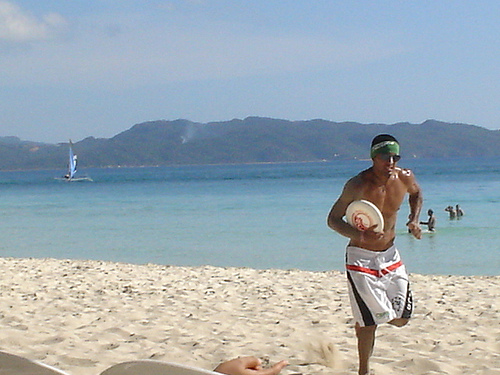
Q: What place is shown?
A: It is a beach.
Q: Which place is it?
A: It is a beach.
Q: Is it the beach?
A: Yes, it is the beach.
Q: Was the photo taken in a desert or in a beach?
A: It was taken at a beach.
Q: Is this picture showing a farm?
A: No, the picture is showing a beach.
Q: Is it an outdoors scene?
A: Yes, it is outdoors.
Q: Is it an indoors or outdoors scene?
A: It is outdoors.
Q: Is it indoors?
A: No, it is outdoors.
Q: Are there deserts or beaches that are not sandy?
A: No, there is a beach but it is sandy.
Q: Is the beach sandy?
A: Yes, the beach is sandy.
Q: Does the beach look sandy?
A: Yes, the beach is sandy.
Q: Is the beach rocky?
A: No, the beach is sandy.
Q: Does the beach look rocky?
A: No, the beach is sandy.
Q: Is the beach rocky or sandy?
A: The beach is sandy.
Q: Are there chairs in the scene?
A: Yes, there is a chair.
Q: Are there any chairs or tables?
A: Yes, there is a chair.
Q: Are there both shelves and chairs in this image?
A: No, there is a chair but no shelves.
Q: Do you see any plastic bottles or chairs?
A: Yes, there is a plastic chair.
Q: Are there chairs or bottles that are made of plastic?
A: Yes, the chair is made of plastic.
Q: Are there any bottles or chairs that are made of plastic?
A: Yes, the chair is made of plastic.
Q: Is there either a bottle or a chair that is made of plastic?
A: Yes, the chair is made of plastic.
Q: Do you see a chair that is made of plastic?
A: Yes, there is a chair that is made of plastic.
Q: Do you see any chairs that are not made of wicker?
A: Yes, there is a chair that is made of plastic.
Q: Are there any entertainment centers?
A: No, there are no entertainment centers.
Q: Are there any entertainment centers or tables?
A: No, there are no entertainment centers or tables.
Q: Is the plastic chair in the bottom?
A: Yes, the chair is in the bottom of the image.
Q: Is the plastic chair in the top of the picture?
A: No, the chair is in the bottom of the image.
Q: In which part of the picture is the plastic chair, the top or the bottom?
A: The chair is in the bottom of the image.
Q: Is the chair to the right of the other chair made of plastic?
A: Yes, the chair is made of plastic.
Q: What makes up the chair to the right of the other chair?
A: The chair is made of plastic.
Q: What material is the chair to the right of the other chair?
A: The chair is made of plastic.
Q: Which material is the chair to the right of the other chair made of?
A: The chair is made of plastic.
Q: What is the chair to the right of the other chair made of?
A: The chair is made of plastic.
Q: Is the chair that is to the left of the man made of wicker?
A: No, the chair is made of plastic.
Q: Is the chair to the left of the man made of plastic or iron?
A: The chair is made of plastic.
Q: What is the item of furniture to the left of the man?
A: The piece of furniture is a chair.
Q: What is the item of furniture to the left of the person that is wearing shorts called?
A: The piece of furniture is a chair.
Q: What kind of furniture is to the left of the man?
A: The piece of furniture is a chair.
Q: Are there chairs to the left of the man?
A: Yes, there is a chair to the left of the man.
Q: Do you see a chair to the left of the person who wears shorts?
A: Yes, there is a chair to the left of the man.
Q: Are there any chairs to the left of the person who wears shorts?
A: Yes, there is a chair to the left of the man.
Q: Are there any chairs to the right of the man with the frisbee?
A: No, the chair is to the left of the man.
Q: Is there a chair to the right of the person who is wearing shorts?
A: No, the chair is to the left of the man.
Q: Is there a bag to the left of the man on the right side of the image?
A: No, there is a chair to the left of the man.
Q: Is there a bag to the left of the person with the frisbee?
A: No, there is a chair to the left of the man.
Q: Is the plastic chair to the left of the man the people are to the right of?
A: Yes, the chair is to the left of the man.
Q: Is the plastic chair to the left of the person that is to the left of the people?
A: Yes, the chair is to the left of the man.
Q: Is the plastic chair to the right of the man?
A: No, the chair is to the left of the man.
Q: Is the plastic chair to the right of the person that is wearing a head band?
A: No, the chair is to the left of the man.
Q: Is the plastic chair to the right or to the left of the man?
A: The chair is to the left of the man.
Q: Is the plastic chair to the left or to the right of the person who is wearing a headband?
A: The chair is to the left of the man.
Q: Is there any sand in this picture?
A: Yes, there is sand.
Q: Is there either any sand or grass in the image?
A: Yes, there is sand.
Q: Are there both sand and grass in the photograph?
A: No, there is sand but no grass.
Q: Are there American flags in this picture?
A: No, there are no American flags.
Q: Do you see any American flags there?
A: No, there are no American flags.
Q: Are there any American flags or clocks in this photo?
A: No, there are no American flags or clocks.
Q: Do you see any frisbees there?
A: Yes, there is a frisbee.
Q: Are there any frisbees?
A: Yes, there is a frisbee.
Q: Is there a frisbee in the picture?
A: Yes, there is a frisbee.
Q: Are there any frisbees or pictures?
A: Yes, there is a frisbee.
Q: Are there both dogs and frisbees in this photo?
A: No, there is a frisbee but no dogs.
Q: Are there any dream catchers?
A: No, there are no dream catchers.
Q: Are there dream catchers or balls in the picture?
A: No, there are no dream catchers or balls.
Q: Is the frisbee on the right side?
A: Yes, the frisbee is on the right of the image.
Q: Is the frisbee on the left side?
A: No, the frisbee is on the right of the image.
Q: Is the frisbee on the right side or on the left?
A: The frisbee is on the right of the image.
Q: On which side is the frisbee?
A: The frisbee is on the right of the image.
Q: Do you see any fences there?
A: No, there are no fences.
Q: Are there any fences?
A: No, there are no fences.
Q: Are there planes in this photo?
A: No, there are no planes.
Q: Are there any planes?
A: No, there are no planes.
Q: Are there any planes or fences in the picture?
A: No, there are no planes or fences.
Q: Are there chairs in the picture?
A: Yes, there is a chair.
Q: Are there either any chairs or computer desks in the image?
A: Yes, there is a chair.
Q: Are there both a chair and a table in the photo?
A: No, there is a chair but no tables.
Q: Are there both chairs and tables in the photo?
A: No, there is a chair but no tables.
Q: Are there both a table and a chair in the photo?
A: No, there is a chair but no tables.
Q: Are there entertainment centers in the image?
A: No, there are no entertainment centers.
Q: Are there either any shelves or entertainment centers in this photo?
A: No, there are no entertainment centers or shelves.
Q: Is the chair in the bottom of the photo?
A: Yes, the chair is in the bottom of the image.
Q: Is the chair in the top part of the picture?
A: No, the chair is in the bottom of the image.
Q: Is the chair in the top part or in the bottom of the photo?
A: The chair is in the bottom of the image.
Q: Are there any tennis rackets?
A: No, there are no tennis rackets.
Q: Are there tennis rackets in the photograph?
A: No, there are no tennis rackets.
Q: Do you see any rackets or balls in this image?
A: No, there are no rackets or balls.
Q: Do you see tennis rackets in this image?
A: No, there are no tennis rackets.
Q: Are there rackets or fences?
A: No, there are no rackets or fences.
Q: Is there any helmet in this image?
A: No, there are no helmets.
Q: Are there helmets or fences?
A: No, there are no helmets or fences.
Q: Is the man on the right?
A: Yes, the man is on the right of the image.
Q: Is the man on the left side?
A: No, the man is on the right of the image.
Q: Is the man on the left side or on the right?
A: The man is on the right of the image.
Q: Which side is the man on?
A: The man is on the right of the image.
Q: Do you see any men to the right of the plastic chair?
A: Yes, there is a man to the right of the chair.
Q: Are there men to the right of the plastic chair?
A: Yes, there is a man to the right of the chair.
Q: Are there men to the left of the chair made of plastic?
A: No, the man is to the right of the chair.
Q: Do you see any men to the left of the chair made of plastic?
A: No, the man is to the right of the chair.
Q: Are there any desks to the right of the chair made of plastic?
A: No, there is a man to the right of the chair.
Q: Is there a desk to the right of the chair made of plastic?
A: No, there is a man to the right of the chair.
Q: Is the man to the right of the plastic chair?
A: Yes, the man is to the right of the chair.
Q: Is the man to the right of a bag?
A: No, the man is to the right of the chair.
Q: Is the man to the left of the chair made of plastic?
A: No, the man is to the right of the chair.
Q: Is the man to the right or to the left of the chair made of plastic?
A: The man is to the right of the chair.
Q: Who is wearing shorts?
A: The man is wearing shorts.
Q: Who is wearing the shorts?
A: The man is wearing shorts.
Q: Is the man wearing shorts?
A: Yes, the man is wearing shorts.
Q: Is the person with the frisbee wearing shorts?
A: Yes, the man is wearing shorts.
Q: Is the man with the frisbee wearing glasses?
A: No, the man is wearing shorts.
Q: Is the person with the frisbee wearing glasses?
A: No, the man is wearing shorts.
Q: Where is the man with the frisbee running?
A: The man is running on the beach.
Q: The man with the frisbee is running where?
A: The man is running on the beach.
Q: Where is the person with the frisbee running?
A: The man is running on the beach.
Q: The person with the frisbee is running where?
A: The man is running on the beach.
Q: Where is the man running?
A: The man is running on the beach.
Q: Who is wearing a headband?
A: The man is wearing a headband.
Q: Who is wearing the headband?
A: The man is wearing a headband.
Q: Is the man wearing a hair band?
A: Yes, the man is wearing a hair band.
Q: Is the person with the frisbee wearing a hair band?
A: Yes, the man is wearing a hair band.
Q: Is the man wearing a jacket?
A: No, the man is wearing a hair band.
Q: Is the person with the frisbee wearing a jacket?
A: No, the man is wearing a hair band.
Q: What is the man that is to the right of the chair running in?
A: The man is running in the sand.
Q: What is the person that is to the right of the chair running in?
A: The man is running in the sand.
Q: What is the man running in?
A: The man is running in the sand.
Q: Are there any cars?
A: No, there are no cars.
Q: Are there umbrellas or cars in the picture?
A: No, there are no cars or umbrellas.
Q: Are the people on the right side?
A: Yes, the people are on the right of the image.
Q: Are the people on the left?
A: No, the people are on the right of the image.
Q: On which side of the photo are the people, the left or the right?
A: The people are on the right of the image.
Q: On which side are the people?
A: The people are on the right of the image.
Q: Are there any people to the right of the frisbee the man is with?
A: Yes, there are people to the right of the frisbee.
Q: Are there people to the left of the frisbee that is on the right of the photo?
A: No, the people are to the right of the frisbee.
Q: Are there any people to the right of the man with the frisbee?
A: Yes, there are people to the right of the man.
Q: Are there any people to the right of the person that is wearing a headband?
A: Yes, there are people to the right of the man.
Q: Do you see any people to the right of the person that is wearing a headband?
A: Yes, there are people to the right of the man.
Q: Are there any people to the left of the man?
A: No, the people are to the right of the man.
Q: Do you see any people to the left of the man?
A: No, the people are to the right of the man.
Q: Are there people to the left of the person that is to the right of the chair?
A: No, the people are to the right of the man.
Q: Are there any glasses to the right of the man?
A: No, there are people to the right of the man.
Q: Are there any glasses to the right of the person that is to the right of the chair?
A: No, there are people to the right of the man.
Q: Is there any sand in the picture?
A: Yes, there is sand.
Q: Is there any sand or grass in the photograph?
A: Yes, there is sand.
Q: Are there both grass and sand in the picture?
A: No, there is sand but no grass.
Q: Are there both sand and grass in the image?
A: No, there is sand but no grass.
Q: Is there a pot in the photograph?
A: No, there are no pots.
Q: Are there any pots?
A: No, there are no pots.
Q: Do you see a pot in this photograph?
A: No, there are no pots.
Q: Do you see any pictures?
A: No, there are no pictures.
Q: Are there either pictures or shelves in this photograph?
A: No, there are no pictures or shelves.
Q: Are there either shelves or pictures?
A: No, there are no pictures or shelves.